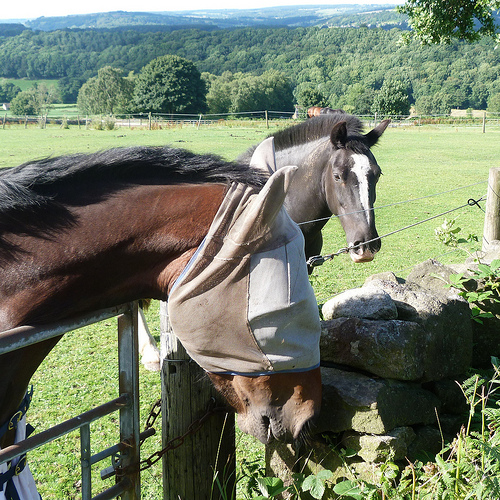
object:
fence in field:
[0, 110, 500, 133]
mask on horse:
[162, 135, 324, 378]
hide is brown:
[0, 183, 170, 252]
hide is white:
[351, 149, 376, 227]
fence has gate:
[1, 295, 143, 499]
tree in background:
[128, 50, 209, 123]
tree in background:
[75, 63, 135, 119]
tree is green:
[371, 66, 416, 121]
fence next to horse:
[0, 160, 500, 497]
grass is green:
[1, 102, 84, 117]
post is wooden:
[159, 288, 240, 500]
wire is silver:
[295, 179, 489, 228]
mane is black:
[0, 144, 279, 229]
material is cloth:
[244, 226, 321, 372]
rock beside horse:
[319, 285, 398, 322]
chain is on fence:
[110, 391, 222, 475]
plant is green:
[433, 213, 499, 328]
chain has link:
[147, 450, 163, 465]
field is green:
[0, 122, 500, 500]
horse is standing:
[224, 109, 393, 277]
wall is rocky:
[315, 247, 500, 484]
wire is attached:
[302, 195, 490, 272]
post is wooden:
[481, 162, 500, 254]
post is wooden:
[266, 109, 270, 129]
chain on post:
[162, 396, 220, 459]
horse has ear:
[0, 135, 324, 500]